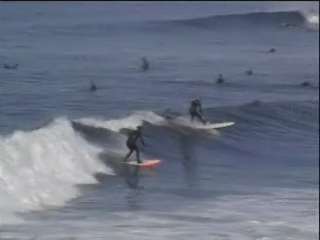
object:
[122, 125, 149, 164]
surfer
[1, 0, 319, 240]
ocean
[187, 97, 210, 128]
surfer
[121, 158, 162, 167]
surfboard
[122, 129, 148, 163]
suit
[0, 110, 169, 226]
wave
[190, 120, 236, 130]
surfboard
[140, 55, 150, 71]
person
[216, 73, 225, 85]
person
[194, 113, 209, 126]
leg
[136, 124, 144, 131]
head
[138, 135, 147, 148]
arm